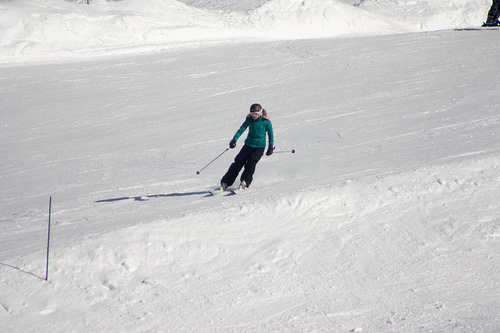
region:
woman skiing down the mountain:
[192, 94, 285, 191]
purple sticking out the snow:
[43, 197, 55, 287]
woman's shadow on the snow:
[103, 184, 215, 202]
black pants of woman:
[220, 150, 261, 179]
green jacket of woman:
[232, 117, 276, 141]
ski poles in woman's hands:
[191, 147, 301, 173]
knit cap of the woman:
[247, 102, 264, 112]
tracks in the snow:
[208, 43, 495, 148]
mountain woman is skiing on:
[7, 54, 494, 331]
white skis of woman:
[204, 179, 239, 201]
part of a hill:
[371, 90, 375, 206]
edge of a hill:
[273, 255, 300, 300]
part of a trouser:
[245, 165, 257, 174]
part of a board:
[213, 181, 225, 193]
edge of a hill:
[398, 151, 416, 191]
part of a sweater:
[254, 129, 265, 142]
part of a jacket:
[256, 138, 261, 148]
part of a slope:
[355, 58, 370, 200]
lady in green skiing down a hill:
[186, 65, 308, 226]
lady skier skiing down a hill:
[181, 85, 298, 197]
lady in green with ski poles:
[159, 55, 324, 242]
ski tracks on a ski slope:
[341, 90, 476, 285]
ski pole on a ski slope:
[41, 178, 71, 284]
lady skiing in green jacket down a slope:
[66, 25, 406, 273]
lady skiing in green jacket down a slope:
[140, 92, 431, 249]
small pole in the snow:
[38, 177, 71, 297]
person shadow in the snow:
[105, 172, 225, 212]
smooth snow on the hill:
[26, 60, 217, 142]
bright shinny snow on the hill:
[227, 190, 457, 286]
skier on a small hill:
[186, 94, 294, 226]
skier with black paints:
[237, 142, 265, 199]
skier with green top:
[234, 117, 279, 154]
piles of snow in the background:
[46, 3, 185, 72]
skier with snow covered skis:
[203, 176, 258, 203]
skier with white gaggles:
[244, 102, 267, 124]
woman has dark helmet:
[227, 96, 275, 130]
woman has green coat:
[237, 129, 272, 141]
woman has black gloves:
[229, 136, 291, 177]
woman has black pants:
[222, 144, 270, 176]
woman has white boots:
[222, 173, 253, 201]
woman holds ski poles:
[188, 126, 300, 172]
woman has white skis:
[204, 143, 286, 198]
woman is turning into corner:
[201, 104, 276, 202]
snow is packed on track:
[267, 29, 488, 173]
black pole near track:
[26, 191, 68, 276]